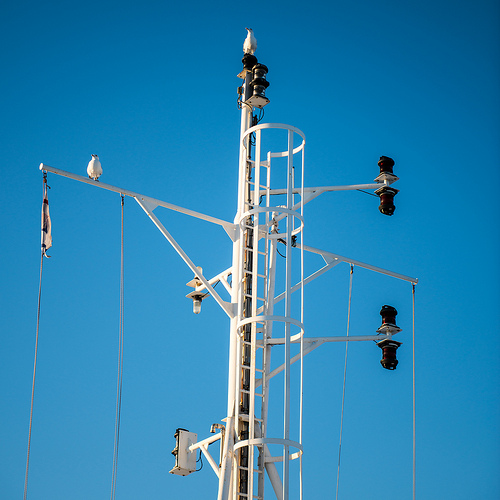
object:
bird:
[243, 27, 258, 55]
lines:
[411, 281, 418, 495]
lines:
[19, 175, 46, 500]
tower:
[17, 23, 421, 500]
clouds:
[0, 0, 500, 500]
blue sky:
[0, 0, 500, 500]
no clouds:
[0, 2, 498, 497]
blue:
[0, 0, 500, 500]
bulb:
[185, 290, 211, 314]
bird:
[87, 153, 102, 182]